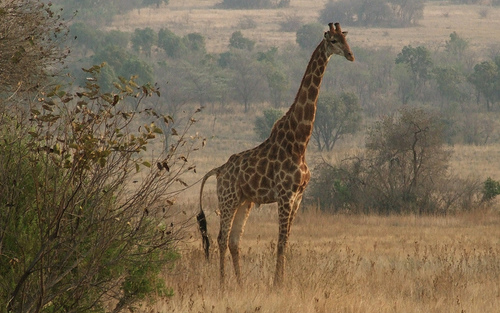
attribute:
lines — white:
[216, 151, 326, 209]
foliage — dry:
[10, 15, 190, 311]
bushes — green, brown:
[0, 1, 215, 308]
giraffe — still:
[189, 10, 365, 295]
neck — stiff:
[230, 45, 352, 135]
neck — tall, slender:
[265, 37, 322, 165]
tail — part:
[175, 184, 225, 271]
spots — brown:
[230, 158, 288, 193]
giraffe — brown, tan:
[197, 21, 354, 287]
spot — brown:
[250, 158, 282, 183]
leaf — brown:
[163, 160, 170, 172]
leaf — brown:
[140, 159, 152, 167]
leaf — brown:
[163, 195, 180, 210]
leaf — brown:
[109, 92, 120, 105]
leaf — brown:
[192, 103, 206, 114]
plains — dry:
[308, 217, 469, 301]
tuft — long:
[195, 208, 212, 265]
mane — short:
[276, 33, 328, 123]